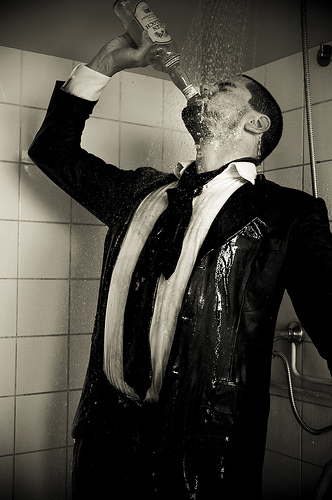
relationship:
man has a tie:
[28, 32, 332, 499] [121, 156, 262, 399]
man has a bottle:
[28, 32, 332, 499] [111, 1, 204, 103]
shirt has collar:
[54, 61, 260, 407] [173, 159, 261, 187]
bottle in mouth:
[111, 1, 204, 103] [183, 91, 204, 107]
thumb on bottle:
[123, 40, 155, 65] [111, 1, 204, 103]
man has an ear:
[28, 32, 332, 499] [245, 114, 274, 135]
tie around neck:
[121, 156, 262, 399] [191, 144, 264, 172]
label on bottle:
[132, 2, 174, 45] [111, 1, 204, 103]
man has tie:
[28, 32, 332, 499] [121, 156, 262, 399]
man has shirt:
[28, 32, 332, 499] [54, 61, 260, 407]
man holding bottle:
[28, 32, 332, 499] [111, 1, 204, 103]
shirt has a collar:
[54, 61, 260, 407] [173, 159, 261, 187]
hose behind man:
[291, 8, 322, 197] [28, 32, 332, 499]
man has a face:
[28, 32, 332, 499] [182, 73, 247, 122]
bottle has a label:
[111, 1, 204, 103] [132, 2, 174, 45]